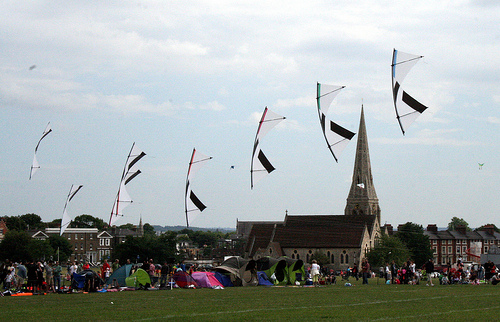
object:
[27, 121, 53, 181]
kite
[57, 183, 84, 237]
kite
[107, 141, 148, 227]
kite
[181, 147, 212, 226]
kite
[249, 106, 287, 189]
kite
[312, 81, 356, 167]
kite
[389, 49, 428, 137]
kite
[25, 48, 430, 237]
row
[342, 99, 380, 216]
steeple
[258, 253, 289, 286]
tent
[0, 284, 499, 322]
grass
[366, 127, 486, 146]
cloud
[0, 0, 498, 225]
sky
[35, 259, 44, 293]
person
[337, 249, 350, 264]
window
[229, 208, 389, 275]
church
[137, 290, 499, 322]
line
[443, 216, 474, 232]
leaves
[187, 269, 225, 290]
tent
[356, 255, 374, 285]
person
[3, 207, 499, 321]
city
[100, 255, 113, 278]
person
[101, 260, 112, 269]
sleeve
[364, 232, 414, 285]
tree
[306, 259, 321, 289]
person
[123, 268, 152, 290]
tent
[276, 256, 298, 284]
tent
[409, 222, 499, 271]
building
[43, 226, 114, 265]
building